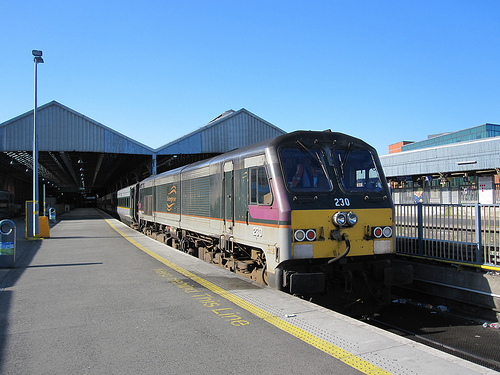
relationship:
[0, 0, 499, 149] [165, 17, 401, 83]
clouds in sky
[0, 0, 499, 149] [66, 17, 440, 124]
clouds in sky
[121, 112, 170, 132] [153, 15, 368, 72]
cloud in sky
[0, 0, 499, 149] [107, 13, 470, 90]
clouds in sky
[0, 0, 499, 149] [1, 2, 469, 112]
clouds in sky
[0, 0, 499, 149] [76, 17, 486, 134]
clouds in sky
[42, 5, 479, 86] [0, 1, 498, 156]
clouds in sky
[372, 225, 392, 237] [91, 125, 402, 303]
lights on side of train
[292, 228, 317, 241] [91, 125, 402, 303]
lights on side of train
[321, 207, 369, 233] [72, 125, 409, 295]
lights in center of train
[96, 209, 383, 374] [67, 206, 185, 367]
line runs along platform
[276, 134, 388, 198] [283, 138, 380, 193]
windows have wipers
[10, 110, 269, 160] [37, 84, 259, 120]
train station has points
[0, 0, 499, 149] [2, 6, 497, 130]
clouds in sky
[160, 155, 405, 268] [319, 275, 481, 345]
train on railroad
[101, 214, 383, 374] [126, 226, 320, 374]
line on platform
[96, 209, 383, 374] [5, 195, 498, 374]
line on platform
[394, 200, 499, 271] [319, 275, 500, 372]
fence beside railroad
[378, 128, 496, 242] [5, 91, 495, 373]
structure at train station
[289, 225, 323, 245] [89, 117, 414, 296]
headlights are on train